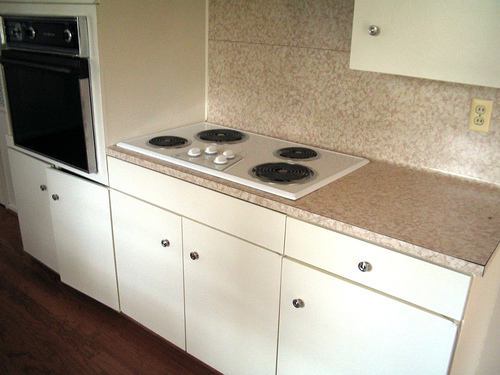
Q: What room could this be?
A: It is a kitchen.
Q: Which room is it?
A: It is a kitchen.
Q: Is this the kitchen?
A: Yes, it is the kitchen.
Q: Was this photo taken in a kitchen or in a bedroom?
A: It was taken at a kitchen.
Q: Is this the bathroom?
A: No, it is the kitchen.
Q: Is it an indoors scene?
A: Yes, it is indoors.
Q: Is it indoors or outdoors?
A: It is indoors.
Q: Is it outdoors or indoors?
A: It is indoors.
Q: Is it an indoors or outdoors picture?
A: It is indoors.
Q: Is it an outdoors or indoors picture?
A: It is indoors.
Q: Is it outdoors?
A: No, it is indoors.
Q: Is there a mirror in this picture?
A: No, there are no mirrors.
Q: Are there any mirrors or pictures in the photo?
A: No, there are no mirrors or pictures.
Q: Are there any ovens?
A: Yes, there is an oven.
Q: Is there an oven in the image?
A: Yes, there is an oven.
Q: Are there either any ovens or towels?
A: Yes, there is an oven.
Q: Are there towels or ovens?
A: Yes, there is an oven.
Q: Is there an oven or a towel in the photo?
A: Yes, there is an oven.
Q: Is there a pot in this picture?
A: No, there are no pots.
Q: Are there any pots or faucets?
A: No, there are no pots or faucets.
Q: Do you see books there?
A: No, there are no books.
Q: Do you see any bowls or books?
A: No, there are no books or bowls.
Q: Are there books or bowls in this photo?
A: No, there are no books or bowls.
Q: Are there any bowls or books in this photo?
A: No, there are no books or bowls.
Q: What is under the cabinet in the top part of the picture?
A: The electric outlet is under the cabinet.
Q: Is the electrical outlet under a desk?
A: No, the electrical outlet is under the cabinet.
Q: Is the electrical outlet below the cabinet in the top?
A: Yes, the electrical outlet is below the cabinet.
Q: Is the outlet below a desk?
A: No, the outlet is below the cabinet.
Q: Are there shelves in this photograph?
A: No, there are no shelves.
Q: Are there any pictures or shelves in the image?
A: No, there are no shelves or pictures.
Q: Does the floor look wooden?
A: Yes, the floor is wooden.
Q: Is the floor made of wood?
A: Yes, the floor is made of wood.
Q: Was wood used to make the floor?
A: Yes, the floor is made of wood.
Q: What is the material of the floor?
A: The floor is made of wood.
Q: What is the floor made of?
A: The floor is made of wood.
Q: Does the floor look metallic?
A: No, the floor is wooden.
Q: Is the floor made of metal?
A: No, the floor is made of wood.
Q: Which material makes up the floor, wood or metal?
A: The floor is made of wood.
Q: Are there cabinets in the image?
A: Yes, there is a cabinet.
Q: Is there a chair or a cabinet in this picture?
A: Yes, there is a cabinet.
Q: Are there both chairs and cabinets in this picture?
A: No, there is a cabinet but no chairs.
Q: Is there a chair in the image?
A: No, there are no chairs.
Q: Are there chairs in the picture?
A: No, there are no chairs.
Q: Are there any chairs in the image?
A: No, there are no chairs.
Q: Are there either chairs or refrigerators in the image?
A: No, there are no chairs or refrigerators.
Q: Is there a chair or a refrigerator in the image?
A: No, there are no chairs or refrigerators.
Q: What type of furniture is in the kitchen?
A: The piece of furniture is a cabinet.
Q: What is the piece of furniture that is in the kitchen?
A: The piece of furniture is a cabinet.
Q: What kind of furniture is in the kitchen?
A: The piece of furniture is a cabinet.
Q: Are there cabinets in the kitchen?
A: Yes, there is a cabinet in the kitchen.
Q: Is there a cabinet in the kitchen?
A: Yes, there is a cabinet in the kitchen.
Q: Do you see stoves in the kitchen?
A: No, there is a cabinet in the kitchen.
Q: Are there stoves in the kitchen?
A: No, there is a cabinet in the kitchen.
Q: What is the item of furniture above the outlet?
A: The piece of furniture is a cabinet.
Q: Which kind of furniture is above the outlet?
A: The piece of furniture is a cabinet.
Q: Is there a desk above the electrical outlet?
A: No, there is a cabinet above the electrical outlet.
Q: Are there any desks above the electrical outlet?
A: No, there is a cabinet above the electrical outlet.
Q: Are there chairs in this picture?
A: No, there are no chairs.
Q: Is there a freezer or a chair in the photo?
A: No, there are no chairs or refrigerators.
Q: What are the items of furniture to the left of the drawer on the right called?
A: The pieces of furniture are cabinets.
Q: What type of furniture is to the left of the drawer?
A: The pieces of furniture are cabinets.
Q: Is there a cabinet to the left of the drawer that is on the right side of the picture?
A: Yes, there are cabinets to the left of the drawer.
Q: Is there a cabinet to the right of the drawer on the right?
A: No, the cabinets are to the left of the drawer.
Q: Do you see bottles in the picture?
A: No, there are no bottles.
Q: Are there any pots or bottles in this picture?
A: No, there are no bottles or pots.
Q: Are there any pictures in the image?
A: No, there are no pictures.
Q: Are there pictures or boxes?
A: No, there are no pictures or boxes.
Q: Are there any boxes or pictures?
A: No, there are no pictures or boxes.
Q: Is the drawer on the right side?
A: Yes, the drawer is on the right of the image.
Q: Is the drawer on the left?
A: No, the drawer is on the right of the image.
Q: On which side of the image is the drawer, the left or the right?
A: The drawer is on the right of the image.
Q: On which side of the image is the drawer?
A: The drawer is on the right of the image.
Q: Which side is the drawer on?
A: The drawer is on the right of the image.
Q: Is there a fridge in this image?
A: No, there are no refrigerators.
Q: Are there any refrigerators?
A: No, there are no refrigerators.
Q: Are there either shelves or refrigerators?
A: No, there are no refrigerators or shelves.